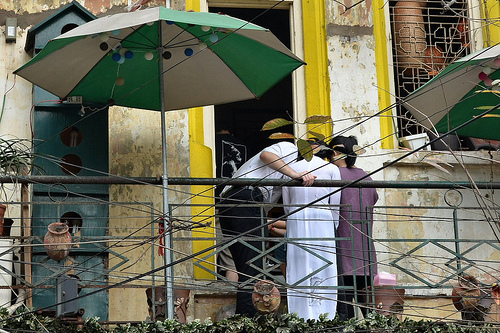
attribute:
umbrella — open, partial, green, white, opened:
[49, 1, 264, 112]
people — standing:
[282, 116, 375, 279]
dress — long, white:
[272, 206, 322, 303]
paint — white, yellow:
[301, 6, 328, 45]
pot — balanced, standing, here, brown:
[40, 222, 73, 253]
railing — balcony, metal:
[80, 177, 161, 185]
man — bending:
[225, 132, 289, 219]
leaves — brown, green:
[190, 319, 212, 328]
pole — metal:
[152, 247, 180, 323]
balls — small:
[147, 44, 181, 63]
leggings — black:
[341, 278, 372, 309]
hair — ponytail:
[337, 144, 358, 168]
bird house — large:
[8, 70, 109, 172]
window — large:
[386, 0, 486, 150]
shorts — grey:
[231, 243, 267, 265]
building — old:
[314, 60, 468, 274]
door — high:
[194, 2, 305, 186]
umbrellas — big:
[67, 8, 468, 124]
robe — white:
[281, 163, 333, 261]